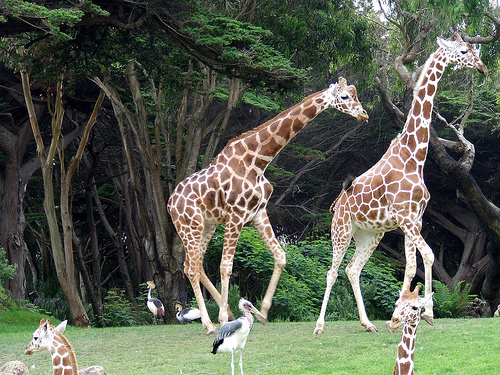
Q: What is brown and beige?
A: Giraffe.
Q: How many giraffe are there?
A: Four.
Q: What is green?
A: Grass.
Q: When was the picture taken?
A: Daytime.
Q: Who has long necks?
A: The giraffe.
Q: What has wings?
A: Birds.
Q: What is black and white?
A: A bird.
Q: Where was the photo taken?
A: In a zoo.